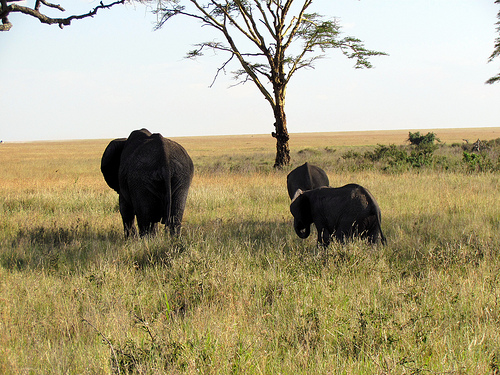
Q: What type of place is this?
A: It is a plain.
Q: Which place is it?
A: It is a plain.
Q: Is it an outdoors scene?
A: Yes, it is outdoors.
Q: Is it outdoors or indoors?
A: It is outdoors.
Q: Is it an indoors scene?
A: No, it is outdoors.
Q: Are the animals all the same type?
A: Yes, all the animals are elephants.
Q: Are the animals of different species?
A: No, all the animals are elephants.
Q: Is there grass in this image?
A: Yes, there is grass.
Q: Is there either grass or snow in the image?
A: Yes, there is grass.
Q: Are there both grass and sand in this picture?
A: No, there is grass but no sand.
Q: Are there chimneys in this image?
A: No, there are no chimneys.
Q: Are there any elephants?
A: Yes, there is an elephant.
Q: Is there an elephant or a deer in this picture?
A: Yes, there is an elephant.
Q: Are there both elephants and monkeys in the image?
A: No, there is an elephant but no monkeys.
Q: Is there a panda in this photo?
A: No, there are no pandas.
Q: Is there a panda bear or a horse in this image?
A: No, there are no pandas or horses.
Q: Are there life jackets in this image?
A: No, there are no life jackets.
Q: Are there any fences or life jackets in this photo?
A: No, there are no life jackets or fences.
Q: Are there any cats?
A: No, there are no cats.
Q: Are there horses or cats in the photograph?
A: No, there are no cats or horses.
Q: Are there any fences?
A: No, there are no fences.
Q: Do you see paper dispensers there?
A: No, there are no paper dispensers.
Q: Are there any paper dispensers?
A: No, there are no paper dispensers.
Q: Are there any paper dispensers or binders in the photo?
A: No, there are no paper dispensers or binders.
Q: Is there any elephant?
A: Yes, there are elephants.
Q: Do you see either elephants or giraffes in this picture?
A: Yes, there are elephants.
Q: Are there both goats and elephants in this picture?
A: No, there are elephants but no goats.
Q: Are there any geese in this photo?
A: No, there are no geese.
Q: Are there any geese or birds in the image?
A: No, there are no geese or birds.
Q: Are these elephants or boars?
A: These are elephants.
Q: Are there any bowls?
A: No, there are no bowls.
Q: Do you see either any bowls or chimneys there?
A: No, there are no bowls or chimneys.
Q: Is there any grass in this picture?
A: Yes, there is grass.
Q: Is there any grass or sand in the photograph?
A: Yes, there is grass.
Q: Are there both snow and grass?
A: No, there is grass but no snow.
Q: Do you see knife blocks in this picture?
A: No, there are no knife blocks.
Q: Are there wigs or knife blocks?
A: No, there are no knife blocks or wigs.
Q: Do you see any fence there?
A: No, there are no fences.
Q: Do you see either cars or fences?
A: No, there are no fences or cars.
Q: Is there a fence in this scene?
A: No, there are no fences.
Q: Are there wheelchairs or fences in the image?
A: No, there are no fences or wheelchairs.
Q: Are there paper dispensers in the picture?
A: No, there are no paper dispensers.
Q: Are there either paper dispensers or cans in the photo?
A: No, there are no paper dispensers or cans.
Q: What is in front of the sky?
A: The twigs are in front of the sky.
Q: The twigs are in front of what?
A: The twigs are in front of the sky.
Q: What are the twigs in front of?
A: The twigs are in front of the sky.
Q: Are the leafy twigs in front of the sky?
A: Yes, the twigs are in front of the sky.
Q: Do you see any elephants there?
A: Yes, there is an elephant.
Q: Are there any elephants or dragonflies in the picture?
A: Yes, there is an elephant.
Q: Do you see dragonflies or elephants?
A: Yes, there is an elephant.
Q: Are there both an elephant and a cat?
A: No, there is an elephant but no cats.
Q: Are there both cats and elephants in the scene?
A: No, there is an elephant but no cats.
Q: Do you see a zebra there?
A: No, there are no zebras.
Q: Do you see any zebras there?
A: No, there are no zebras.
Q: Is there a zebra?
A: No, there are no zebras.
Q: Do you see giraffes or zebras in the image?
A: No, there are no zebras or giraffes.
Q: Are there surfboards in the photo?
A: No, there are no surfboards.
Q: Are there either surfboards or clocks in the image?
A: No, there are no surfboards or clocks.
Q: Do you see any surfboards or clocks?
A: No, there are no surfboards or clocks.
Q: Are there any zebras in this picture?
A: No, there are no zebras.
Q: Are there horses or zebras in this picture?
A: No, there are no zebras or horses.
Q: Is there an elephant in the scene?
A: Yes, there is an elephant.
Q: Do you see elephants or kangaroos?
A: Yes, there is an elephant.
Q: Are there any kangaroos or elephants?
A: Yes, there is an elephant.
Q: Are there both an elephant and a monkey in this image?
A: No, there is an elephant but no monkeys.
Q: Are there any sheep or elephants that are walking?
A: Yes, the elephant is walking.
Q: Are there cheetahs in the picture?
A: No, there are no cheetahs.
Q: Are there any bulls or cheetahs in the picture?
A: No, there are no cheetahs or bulls.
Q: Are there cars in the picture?
A: No, there are no cars.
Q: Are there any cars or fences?
A: No, there are no cars or fences.